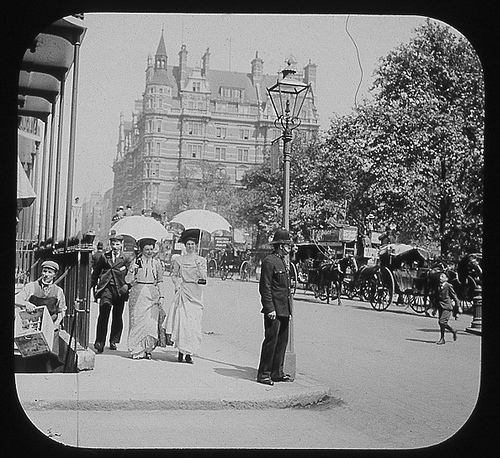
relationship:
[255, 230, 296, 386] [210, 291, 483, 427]
man near street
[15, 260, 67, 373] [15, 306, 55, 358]
man with crate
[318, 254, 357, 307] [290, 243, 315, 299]
horse pulling carriage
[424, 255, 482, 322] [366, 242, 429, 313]
horse pulling carriage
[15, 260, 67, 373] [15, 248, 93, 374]
man on stairs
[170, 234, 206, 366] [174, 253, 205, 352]
woman holding dress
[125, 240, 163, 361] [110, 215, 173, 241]
woman with umbrella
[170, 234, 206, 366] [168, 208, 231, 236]
woman with umbrella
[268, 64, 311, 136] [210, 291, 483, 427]
light near street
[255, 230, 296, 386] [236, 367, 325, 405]
man on corner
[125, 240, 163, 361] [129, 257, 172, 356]
woman in dress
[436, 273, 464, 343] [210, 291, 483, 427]
boy on street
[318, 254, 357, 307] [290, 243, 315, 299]
horse with carriage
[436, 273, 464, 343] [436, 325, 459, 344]
boy in knickers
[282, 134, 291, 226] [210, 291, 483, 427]
post near street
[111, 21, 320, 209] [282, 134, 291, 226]
building behind post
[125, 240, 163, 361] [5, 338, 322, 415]
woman on sidewalk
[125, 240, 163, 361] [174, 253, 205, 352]
woman in dress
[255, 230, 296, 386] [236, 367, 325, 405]
man near corner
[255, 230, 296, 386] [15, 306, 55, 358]
man with crate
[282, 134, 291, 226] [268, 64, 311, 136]
post with light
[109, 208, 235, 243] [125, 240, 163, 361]
umbrellas above woman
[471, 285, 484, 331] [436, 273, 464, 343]
hydrant near boy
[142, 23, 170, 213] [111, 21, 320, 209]
tower on building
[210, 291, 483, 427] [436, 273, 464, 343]
street with a boy crossing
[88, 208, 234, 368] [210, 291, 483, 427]
crowd near street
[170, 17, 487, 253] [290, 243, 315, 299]
trees near carriage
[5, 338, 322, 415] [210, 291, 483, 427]
sidewalk near street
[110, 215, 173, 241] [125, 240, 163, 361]
umbrella over woman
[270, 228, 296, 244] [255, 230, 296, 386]
hat on man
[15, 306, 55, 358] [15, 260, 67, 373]
crate held by man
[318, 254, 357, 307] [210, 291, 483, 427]
horse on street